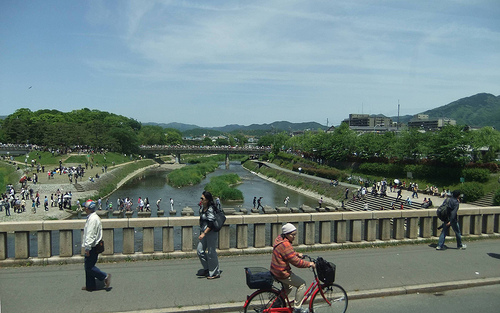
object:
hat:
[281, 222, 298, 235]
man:
[80, 201, 112, 293]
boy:
[269, 222, 316, 248]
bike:
[239, 254, 350, 313]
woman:
[192, 189, 227, 281]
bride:
[0, 219, 499, 307]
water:
[76, 160, 332, 216]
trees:
[38, 120, 89, 155]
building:
[342, 113, 396, 134]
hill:
[413, 92, 500, 130]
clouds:
[141, 26, 265, 68]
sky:
[0, 1, 500, 127]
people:
[97, 197, 104, 211]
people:
[360, 188, 367, 201]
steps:
[368, 192, 423, 205]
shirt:
[81, 212, 104, 250]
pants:
[83, 240, 106, 291]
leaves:
[42, 120, 47, 123]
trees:
[217, 186, 244, 204]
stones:
[112, 210, 122, 216]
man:
[435, 189, 467, 250]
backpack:
[435, 198, 456, 223]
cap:
[81, 199, 98, 210]